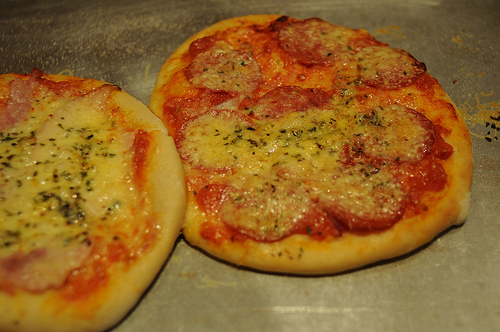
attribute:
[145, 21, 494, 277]
pizza — mini, pepperoni, brown, seasoned, small, cheese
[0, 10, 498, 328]
table — metal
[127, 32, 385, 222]
pan — silver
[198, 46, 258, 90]
pepperoni — red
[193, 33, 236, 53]
tomatoes — red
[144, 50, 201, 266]
dough — beige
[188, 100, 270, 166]
cheese — melted